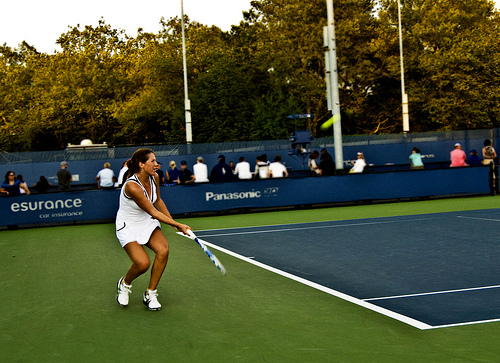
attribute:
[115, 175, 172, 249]
outfit — white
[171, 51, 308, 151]
trees — green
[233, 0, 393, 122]
trees — green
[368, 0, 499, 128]
trees — green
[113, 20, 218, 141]
trees — green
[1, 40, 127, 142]
trees — green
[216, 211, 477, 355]
court — blue, green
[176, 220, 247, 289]
racket — white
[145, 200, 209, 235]
hands — Blue 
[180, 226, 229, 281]
tennis racket — blue, silver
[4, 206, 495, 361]
turf — Green artificial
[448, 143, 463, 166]
person — Back 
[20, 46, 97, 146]
tree — Fall coloring 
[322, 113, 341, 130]
ball — flying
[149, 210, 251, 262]
racket — Tennis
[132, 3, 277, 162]
tree — background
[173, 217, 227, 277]
racquet — white tennis 